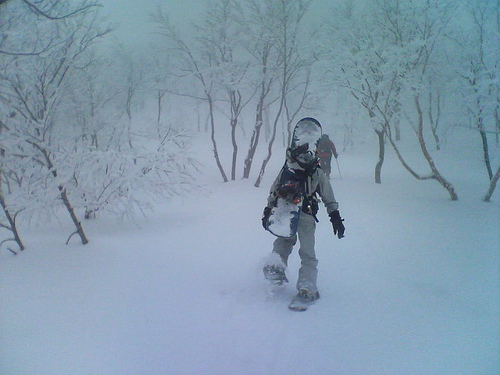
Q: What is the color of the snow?
A: White.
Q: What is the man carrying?
A: Snowboard.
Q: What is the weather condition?
A: Snowing.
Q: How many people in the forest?
A: Two.